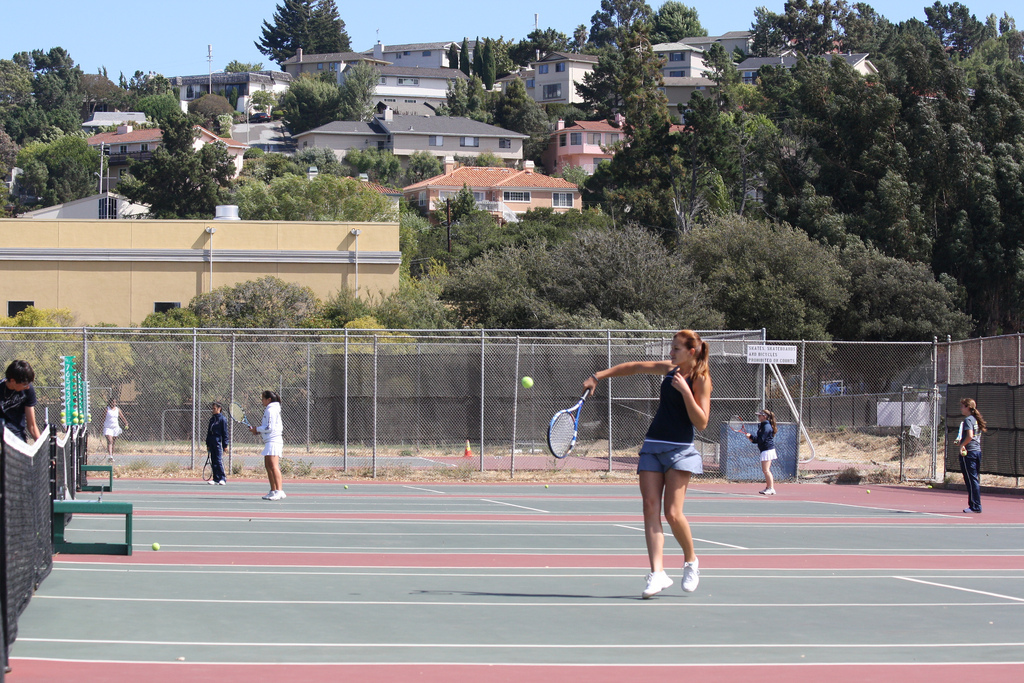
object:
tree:
[255, 0, 354, 68]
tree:
[610, 34, 671, 151]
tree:
[184, 94, 234, 136]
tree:
[687, 91, 789, 218]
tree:
[673, 213, 851, 379]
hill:
[0, 0, 1022, 342]